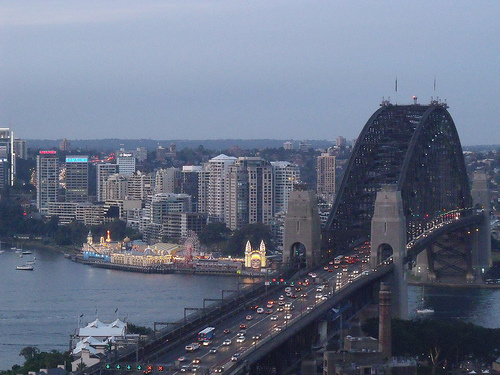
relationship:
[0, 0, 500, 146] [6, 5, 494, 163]
clouds in blue sky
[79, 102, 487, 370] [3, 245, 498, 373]
bridge spanning river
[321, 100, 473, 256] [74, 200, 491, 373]
arch of bridge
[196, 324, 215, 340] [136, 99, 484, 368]
bus travelling down bridge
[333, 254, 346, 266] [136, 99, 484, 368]
bus travelling down bridge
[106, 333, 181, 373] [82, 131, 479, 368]
traffic signals on bridge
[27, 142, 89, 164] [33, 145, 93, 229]
signs atop buildings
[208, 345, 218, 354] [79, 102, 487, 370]
car on bridge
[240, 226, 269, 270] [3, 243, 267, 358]
building near water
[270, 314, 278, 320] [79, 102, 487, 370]
vehicle on bridge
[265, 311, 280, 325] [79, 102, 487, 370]
vehicle on bridge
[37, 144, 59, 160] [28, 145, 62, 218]
red roof on building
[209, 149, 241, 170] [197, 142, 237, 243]
roof on building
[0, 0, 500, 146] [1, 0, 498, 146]
clouds in blue sky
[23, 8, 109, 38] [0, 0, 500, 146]
clouds in clouds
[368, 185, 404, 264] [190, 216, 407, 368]
stone pillars supporting bridge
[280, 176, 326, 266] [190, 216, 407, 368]
stone pillars supporting bridge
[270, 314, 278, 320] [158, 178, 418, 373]
vehicle on bridge